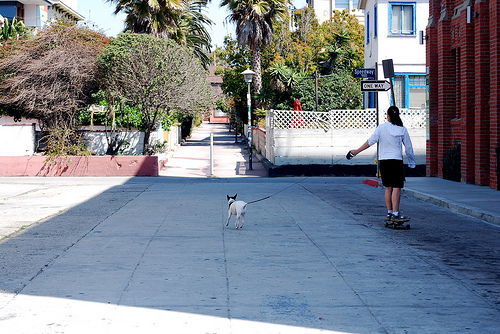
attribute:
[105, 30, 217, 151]
tree — in a city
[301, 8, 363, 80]
tree — in a city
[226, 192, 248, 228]
dog — small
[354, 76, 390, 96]
sign — black, white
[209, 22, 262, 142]
tree — in a city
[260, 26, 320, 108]
tree — in a city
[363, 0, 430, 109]
building — white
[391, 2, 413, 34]
window — blue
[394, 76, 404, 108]
window — blue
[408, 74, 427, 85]
window — blue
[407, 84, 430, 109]
window — blue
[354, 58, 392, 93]
street sign — green and white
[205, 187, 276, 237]
small dog — white and black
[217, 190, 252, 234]
dog — white, black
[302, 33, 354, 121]
tree — in a city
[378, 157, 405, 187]
shorts — black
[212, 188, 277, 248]
dog — white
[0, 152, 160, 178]
wall — red, short